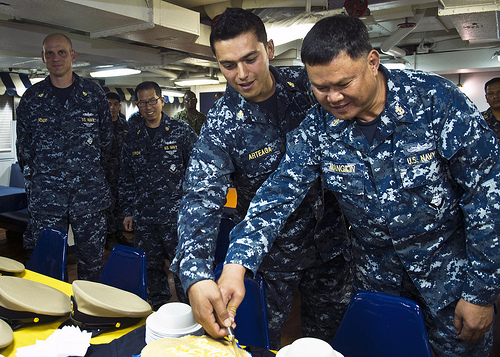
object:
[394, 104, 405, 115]
insignia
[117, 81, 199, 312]
man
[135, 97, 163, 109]
glasses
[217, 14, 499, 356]
men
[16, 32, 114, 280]
navy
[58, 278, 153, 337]
hats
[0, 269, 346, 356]
table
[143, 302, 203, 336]
bowl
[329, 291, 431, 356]
chairs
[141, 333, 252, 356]
cake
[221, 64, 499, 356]
uniform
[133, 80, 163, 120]
head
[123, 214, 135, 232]
hand